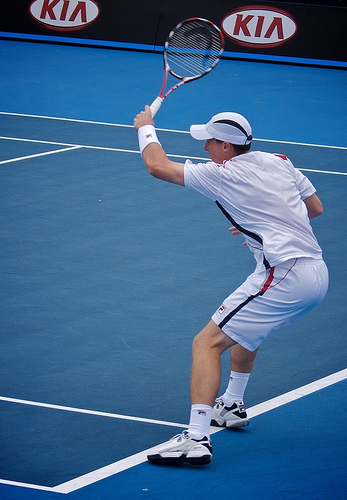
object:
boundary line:
[1, 113, 347, 175]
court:
[1, 32, 346, 500]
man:
[134, 104, 329, 463]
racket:
[140, 17, 224, 119]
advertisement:
[220, 5, 297, 50]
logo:
[184, 26, 212, 69]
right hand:
[227, 227, 248, 246]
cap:
[189, 112, 253, 146]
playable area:
[0, 112, 346, 498]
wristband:
[136, 125, 162, 157]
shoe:
[146, 430, 213, 464]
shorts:
[210, 258, 329, 353]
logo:
[27, 0, 101, 31]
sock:
[189, 403, 214, 441]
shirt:
[182, 150, 323, 273]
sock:
[225, 370, 249, 405]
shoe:
[212, 397, 249, 428]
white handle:
[149, 96, 164, 121]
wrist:
[136, 128, 158, 133]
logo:
[217, 304, 227, 315]